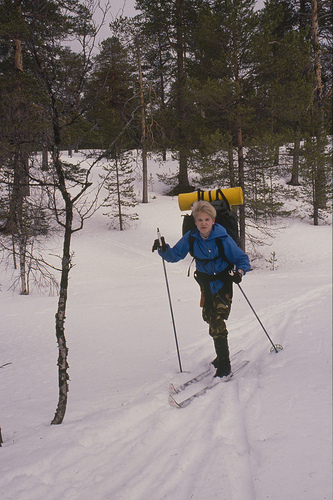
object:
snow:
[0, 133, 333, 474]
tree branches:
[244, 116, 297, 220]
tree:
[108, 12, 160, 209]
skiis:
[167, 349, 249, 408]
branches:
[0, 0, 171, 298]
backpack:
[178, 187, 243, 252]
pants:
[202, 277, 233, 340]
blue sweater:
[158, 222, 251, 301]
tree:
[98, 148, 139, 231]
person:
[151, 199, 250, 378]